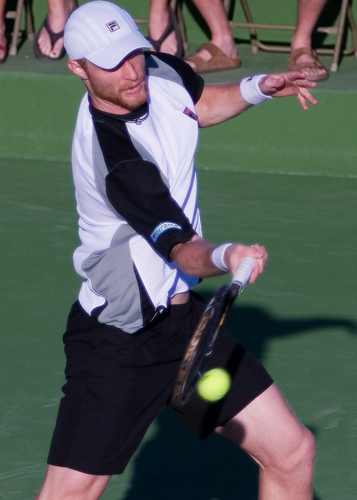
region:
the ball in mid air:
[196, 366, 229, 401]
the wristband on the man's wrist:
[211, 241, 231, 272]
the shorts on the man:
[47, 298, 273, 475]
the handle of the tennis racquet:
[232, 244, 260, 290]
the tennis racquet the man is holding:
[171, 245, 264, 408]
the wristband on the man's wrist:
[240, 73, 274, 105]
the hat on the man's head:
[63, 0, 152, 68]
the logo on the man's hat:
[106, 20, 120, 32]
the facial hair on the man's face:
[81, 64, 149, 109]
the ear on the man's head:
[66, 58, 87, 78]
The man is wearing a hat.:
[61, 3, 166, 70]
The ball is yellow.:
[196, 367, 225, 401]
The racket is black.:
[163, 253, 254, 401]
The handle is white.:
[232, 256, 255, 279]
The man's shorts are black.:
[48, 297, 278, 467]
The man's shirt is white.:
[64, 106, 206, 323]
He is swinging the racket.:
[45, 11, 308, 363]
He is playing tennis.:
[33, 15, 337, 498]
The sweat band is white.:
[232, 69, 272, 110]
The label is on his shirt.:
[142, 216, 182, 242]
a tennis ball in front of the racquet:
[171, 246, 256, 407]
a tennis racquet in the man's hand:
[173, 237, 265, 406]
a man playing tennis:
[37, 6, 314, 498]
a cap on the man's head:
[61, 0, 164, 111]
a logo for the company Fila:
[104, 20, 121, 33]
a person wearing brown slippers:
[185, 42, 329, 80]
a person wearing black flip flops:
[33, 12, 183, 64]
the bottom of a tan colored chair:
[215, 0, 354, 82]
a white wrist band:
[209, 240, 235, 272]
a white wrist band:
[238, 71, 272, 106]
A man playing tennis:
[31, 1, 329, 495]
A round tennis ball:
[192, 364, 233, 405]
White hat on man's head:
[54, 1, 156, 70]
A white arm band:
[201, 238, 237, 274]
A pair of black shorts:
[44, 292, 275, 478]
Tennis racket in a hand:
[164, 239, 270, 416]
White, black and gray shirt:
[65, 50, 214, 336]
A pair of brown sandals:
[182, 37, 331, 89]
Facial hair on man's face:
[85, 67, 154, 112]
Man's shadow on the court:
[121, 300, 354, 496]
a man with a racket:
[38, 3, 282, 420]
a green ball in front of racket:
[188, 365, 245, 409]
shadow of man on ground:
[122, 276, 349, 498]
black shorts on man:
[37, 300, 332, 461]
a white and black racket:
[146, 258, 322, 439]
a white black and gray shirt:
[53, 77, 257, 337]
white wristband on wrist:
[206, 231, 260, 307]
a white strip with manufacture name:
[142, 216, 187, 243]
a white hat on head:
[61, 9, 164, 81]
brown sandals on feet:
[177, 33, 343, 86]